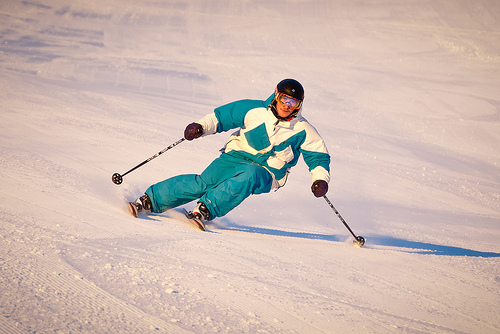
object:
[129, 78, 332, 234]
man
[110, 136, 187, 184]
poles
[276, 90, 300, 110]
goggles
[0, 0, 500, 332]
ground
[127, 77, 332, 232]
woman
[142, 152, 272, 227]
trousers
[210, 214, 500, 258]
shadow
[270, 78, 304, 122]
hat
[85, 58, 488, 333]
slope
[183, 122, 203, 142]
gloves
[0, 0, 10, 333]
edges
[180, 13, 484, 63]
loops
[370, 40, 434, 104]
pieces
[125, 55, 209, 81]
mark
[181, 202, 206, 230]
skis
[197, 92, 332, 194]
coat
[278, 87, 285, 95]
part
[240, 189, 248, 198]
edges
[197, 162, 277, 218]
leg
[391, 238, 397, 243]
part